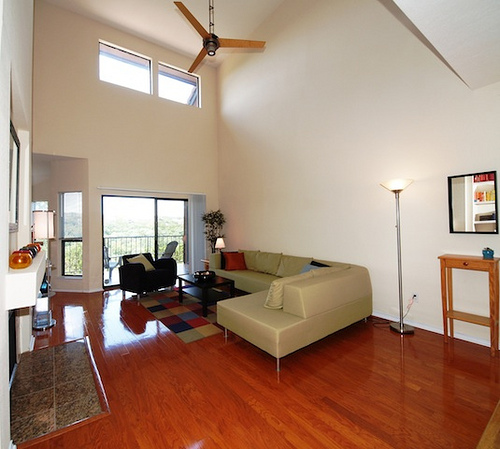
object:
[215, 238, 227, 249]
lamp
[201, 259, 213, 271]
table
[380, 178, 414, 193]
lamp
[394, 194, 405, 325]
pole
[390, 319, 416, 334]
base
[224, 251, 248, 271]
pillow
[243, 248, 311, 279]
cushion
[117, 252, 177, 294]
chair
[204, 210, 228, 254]
plant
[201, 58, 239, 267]
corner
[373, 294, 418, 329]
power cord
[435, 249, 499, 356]
wooden table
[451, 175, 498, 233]
mirror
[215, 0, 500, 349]
wall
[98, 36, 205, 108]
window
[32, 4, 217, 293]
wall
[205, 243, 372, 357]
sofa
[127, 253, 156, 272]
pillow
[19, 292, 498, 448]
floor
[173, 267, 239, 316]
coffee table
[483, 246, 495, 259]
container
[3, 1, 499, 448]
living room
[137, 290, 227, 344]
rug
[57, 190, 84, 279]
window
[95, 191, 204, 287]
window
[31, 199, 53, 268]
window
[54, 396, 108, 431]
tile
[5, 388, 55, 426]
tile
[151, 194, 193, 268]
sliding pane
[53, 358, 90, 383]
tile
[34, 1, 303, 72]
ceiling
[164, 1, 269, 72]
fan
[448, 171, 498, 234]
frame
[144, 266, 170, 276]
seat